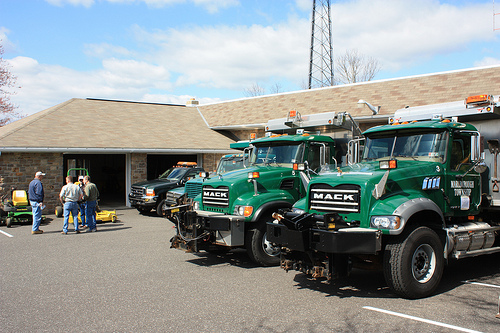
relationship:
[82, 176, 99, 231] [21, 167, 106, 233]
man in group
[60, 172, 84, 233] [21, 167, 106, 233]
man in group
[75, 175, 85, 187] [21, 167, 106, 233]
man in group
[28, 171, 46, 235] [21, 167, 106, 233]
man in group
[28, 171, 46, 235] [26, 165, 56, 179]
man in cap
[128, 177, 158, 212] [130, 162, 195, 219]
front of truck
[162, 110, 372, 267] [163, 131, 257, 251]
green truck next to truck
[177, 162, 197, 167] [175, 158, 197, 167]
light bar with light bar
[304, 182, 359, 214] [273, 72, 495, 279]
emblem on truck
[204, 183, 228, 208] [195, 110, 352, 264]
mack emblem on truck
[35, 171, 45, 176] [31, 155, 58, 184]
cap on head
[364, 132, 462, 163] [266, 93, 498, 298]
windshield of truck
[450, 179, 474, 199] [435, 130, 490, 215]
white print on door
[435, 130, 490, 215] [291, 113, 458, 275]
door of truck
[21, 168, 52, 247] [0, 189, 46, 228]
man standing in front of equipment